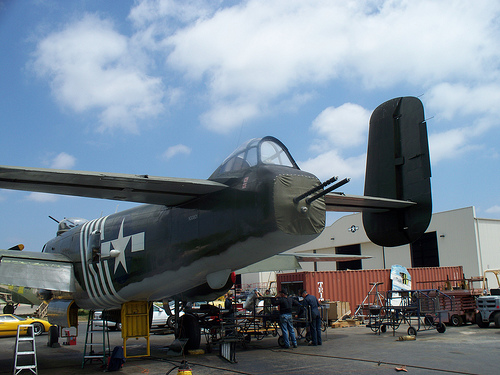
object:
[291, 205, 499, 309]
hangar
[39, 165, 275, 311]
background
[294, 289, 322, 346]
man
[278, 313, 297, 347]
blue jeans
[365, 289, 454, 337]
scaffolding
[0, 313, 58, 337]
car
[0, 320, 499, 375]
road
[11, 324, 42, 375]
ladder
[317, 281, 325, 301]
letters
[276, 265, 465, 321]
container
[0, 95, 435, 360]
airplane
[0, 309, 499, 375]
runway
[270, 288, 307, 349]
man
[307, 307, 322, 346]
pants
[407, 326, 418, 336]
black wheels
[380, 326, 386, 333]
black wheels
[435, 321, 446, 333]
black wheels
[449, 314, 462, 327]
black wheels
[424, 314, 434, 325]
black wheels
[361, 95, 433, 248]
mirror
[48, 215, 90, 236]
propeller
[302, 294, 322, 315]
blue shirt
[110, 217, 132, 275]
star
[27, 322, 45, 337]
tire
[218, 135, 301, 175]
domed window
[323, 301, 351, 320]
boxes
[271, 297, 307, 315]
shirt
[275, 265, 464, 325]
dumpster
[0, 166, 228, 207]
wing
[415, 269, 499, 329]
forklift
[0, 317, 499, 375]
ground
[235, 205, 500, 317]
building